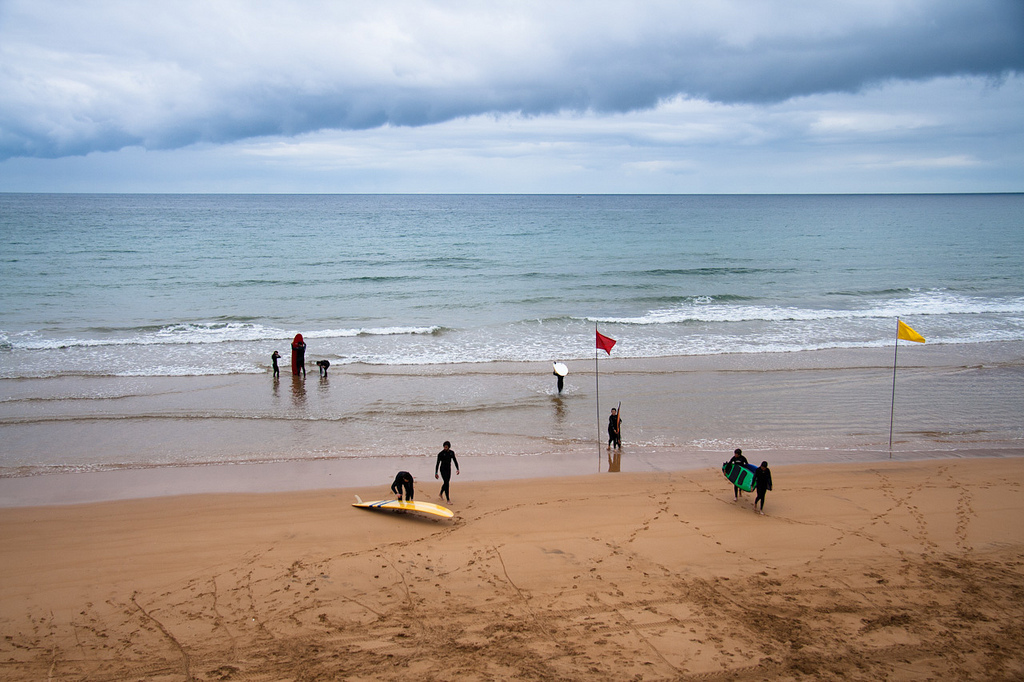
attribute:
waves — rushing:
[23, 297, 1016, 370]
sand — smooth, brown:
[20, 447, 1020, 679]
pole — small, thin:
[886, 316, 903, 463]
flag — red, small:
[590, 329, 614, 355]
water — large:
[2, 194, 1021, 461]